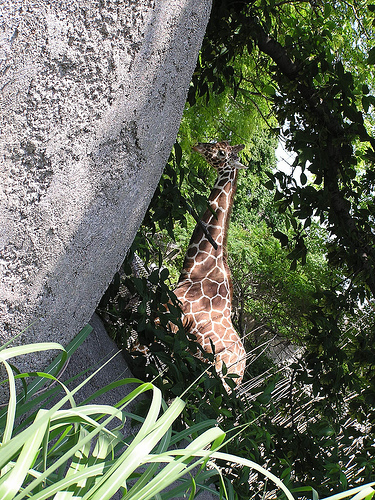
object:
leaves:
[262, 123, 347, 274]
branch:
[245, 3, 295, 71]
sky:
[278, 143, 317, 184]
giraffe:
[166, 134, 273, 394]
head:
[194, 131, 251, 177]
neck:
[186, 172, 244, 256]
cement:
[2, 0, 214, 395]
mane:
[225, 172, 241, 280]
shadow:
[135, 1, 213, 276]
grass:
[0, 338, 276, 498]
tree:
[221, 6, 374, 218]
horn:
[232, 149, 244, 161]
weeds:
[2, 293, 374, 496]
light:
[214, 195, 237, 348]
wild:
[132, 17, 374, 464]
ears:
[222, 143, 250, 172]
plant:
[238, 332, 365, 474]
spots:
[192, 253, 222, 331]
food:
[177, 143, 199, 203]